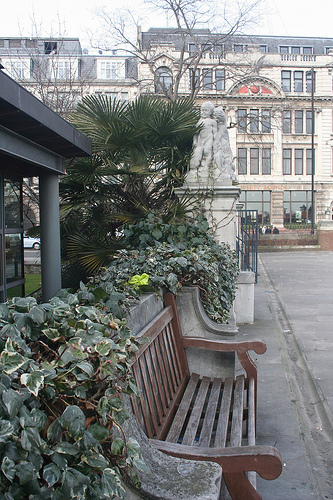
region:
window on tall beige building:
[238, 108, 248, 134]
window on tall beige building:
[250, 109, 258, 131]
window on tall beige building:
[261, 108, 269, 133]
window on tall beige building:
[283, 110, 291, 133]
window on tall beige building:
[293, 109, 302, 132]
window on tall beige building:
[283, 149, 290, 174]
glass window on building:
[308, 202, 313, 221]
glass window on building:
[291, 201, 306, 223]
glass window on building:
[307, 190, 312, 201]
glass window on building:
[291, 190, 305, 199]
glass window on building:
[283, 190, 289, 200]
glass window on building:
[263, 201, 268, 223]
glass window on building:
[261, 191, 270, 200]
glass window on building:
[246, 190, 262, 201]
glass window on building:
[238, 190, 245, 200]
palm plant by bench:
[44, 92, 203, 243]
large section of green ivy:
[22, 279, 106, 486]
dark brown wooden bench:
[108, 277, 290, 480]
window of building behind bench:
[0, 179, 57, 288]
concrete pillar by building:
[22, 157, 73, 305]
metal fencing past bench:
[224, 195, 260, 282]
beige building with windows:
[241, 144, 321, 233]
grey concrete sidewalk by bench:
[259, 269, 314, 459]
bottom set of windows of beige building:
[230, 189, 314, 231]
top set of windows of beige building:
[231, 142, 319, 178]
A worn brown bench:
[112, 292, 276, 494]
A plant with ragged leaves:
[19, 306, 113, 414]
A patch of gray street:
[280, 260, 331, 308]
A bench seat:
[180, 377, 248, 445]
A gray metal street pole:
[34, 185, 67, 291]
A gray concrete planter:
[160, 286, 244, 373]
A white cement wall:
[233, 270, 262, 336]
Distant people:
[254, 222, 282, 236]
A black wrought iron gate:
[239, 209, 262, 269]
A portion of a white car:
[22, 229, 39, 251]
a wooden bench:
[109, 287, 285, 498]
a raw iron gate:
[237, 206, 260, 284]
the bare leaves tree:
[2, 0, 299, 203]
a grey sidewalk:
[237, 249, 328, 499]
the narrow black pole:
[309, 64, 314, 234]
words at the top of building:
[188, 51, 318, 60]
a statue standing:
[170, 100, 242, 275]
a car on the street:
[6, 230, 40, 249]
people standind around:
[257, 223, 279, 236]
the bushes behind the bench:
[2, 269, 179, 499]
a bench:
[138, 354, 254, 441]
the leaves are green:
[43, 432, 92, 482]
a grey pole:
[38, 192, 68, 291]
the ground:
[290, 284, 317, 329]